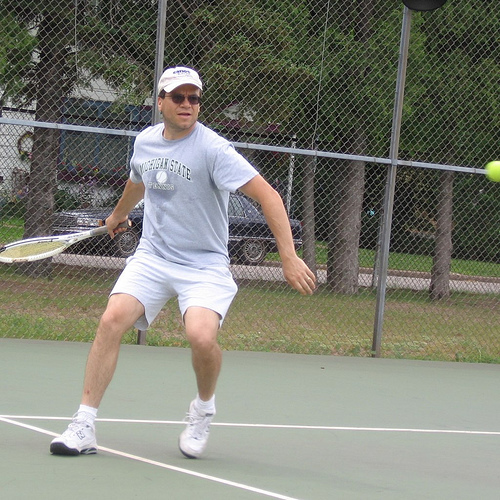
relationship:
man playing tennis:
[39, 50, 322, 497] [2, 128, 499, 305]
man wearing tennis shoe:
[39, 50, 322, 497] [49, 417, 99, 457]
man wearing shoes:
[39, 50, 322, 497] [174, 399, 219, 462]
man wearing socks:
[39, 50, 322, 497] [79, 407, 100, 421]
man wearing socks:
[39, 50, 322, 497] [194, 396, 219, 413]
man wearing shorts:
[39, 50, 322, 497] [102, 250, 245, 331]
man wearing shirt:
[39, 50, 322, 497] [122, 133, 256, 267]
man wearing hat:
[39, 50, 322, 497] [156, 64, 205, 98]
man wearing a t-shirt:
[39, 50, 322, 497] [122, 133, 256, 267]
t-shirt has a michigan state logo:
[122, 133, 256, 267] [141, 157, 197, 202]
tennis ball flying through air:
[476, 161, 500, 180] [312, 117, 437, 219]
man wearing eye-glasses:
[39, 50, 322, 497] [164, 91, 204, 108]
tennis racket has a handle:
[0, 225, 125, 269] [96, 226, 129, 238]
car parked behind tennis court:
[42, 174, 310, 273] [4, 1, 491, 493]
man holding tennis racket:
[39, 50, 322, 497] [0, 225, 125, 269]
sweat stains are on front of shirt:
[150, 181, 173, 227] [122, 133, 256, 267]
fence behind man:
[0, 5, 492, 358] [39, 50, 322, 497]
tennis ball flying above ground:
[476, 161, 500, 180] [9, 368, 499, 498]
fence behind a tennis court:
[0, 5, 492, 358] [4, 1, 491, 493]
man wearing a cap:
[39, 50, 322, 497] [156, 64, 205, 98]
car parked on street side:
[42, 174, 310, 273] [11, 236, 500, 284]